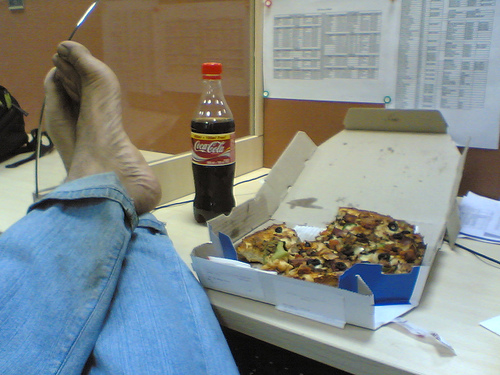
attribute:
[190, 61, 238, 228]
soda bottle — full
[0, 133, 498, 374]
desk — light, wood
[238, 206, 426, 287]
pizza — small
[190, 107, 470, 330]
box — cardboard, open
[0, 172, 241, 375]
jeans — blue, cuffed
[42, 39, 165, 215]
feet — bare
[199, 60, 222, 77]
lid — red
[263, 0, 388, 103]
paper — white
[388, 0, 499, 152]
paper — white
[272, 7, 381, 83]
print — black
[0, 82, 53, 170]
bag — black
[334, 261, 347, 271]
olive — black